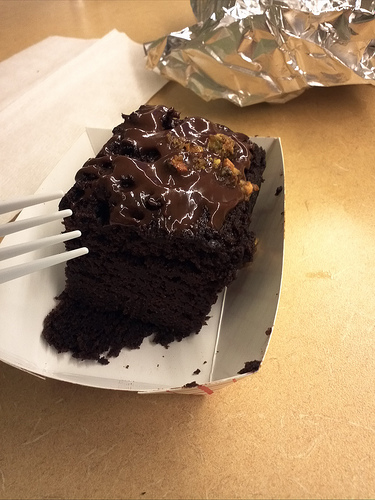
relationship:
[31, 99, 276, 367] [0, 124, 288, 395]
cake in tray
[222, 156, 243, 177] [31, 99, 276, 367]
nut on top of cake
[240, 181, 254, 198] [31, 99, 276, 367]
nut on top of cake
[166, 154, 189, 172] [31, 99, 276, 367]
nut on top of cake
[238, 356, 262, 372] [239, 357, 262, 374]
piece of cake on corner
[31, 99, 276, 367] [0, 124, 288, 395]
cake in paper tray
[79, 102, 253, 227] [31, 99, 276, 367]
chocolate icing on cake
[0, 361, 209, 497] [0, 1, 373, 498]
shadow on table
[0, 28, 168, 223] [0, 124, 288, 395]
napkin next to tray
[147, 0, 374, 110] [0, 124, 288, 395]
tinfoil next to tray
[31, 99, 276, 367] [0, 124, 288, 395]
cake inside tray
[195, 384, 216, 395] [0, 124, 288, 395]
stripe on tray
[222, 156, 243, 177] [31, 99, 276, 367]
nut on cake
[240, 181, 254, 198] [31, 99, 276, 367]
nut on cake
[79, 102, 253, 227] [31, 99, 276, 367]
frosting on cake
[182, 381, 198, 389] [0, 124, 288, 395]
brownie crumbs on tray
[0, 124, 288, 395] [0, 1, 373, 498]
tray on counter top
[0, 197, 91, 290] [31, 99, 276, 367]
fork near cake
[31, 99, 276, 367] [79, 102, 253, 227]
cake has frosting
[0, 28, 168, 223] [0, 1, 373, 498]
napkin on counter top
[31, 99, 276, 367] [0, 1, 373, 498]
cake on counter top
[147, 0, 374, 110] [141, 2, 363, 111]
outer part belonging to paper